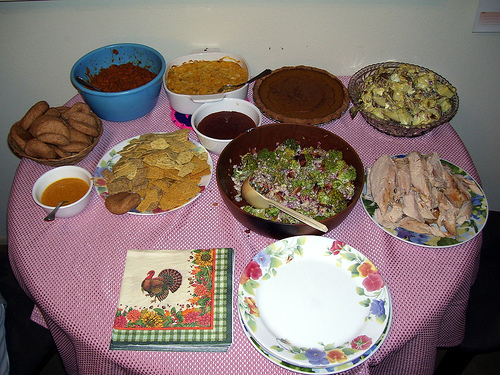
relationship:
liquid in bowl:
[199, 110, 253, 140] [24, 163, 96, 229]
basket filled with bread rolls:
[27, 115, 104, 165] [6, 100, 95, 160]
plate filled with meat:
[368, 152, 488, 246] [373, 153, 473, 237]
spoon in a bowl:
[240, 177, 329, 233] [212, 121, 369, 246]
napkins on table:
[73, 220, 258, 368] [25, 227, 110, 323]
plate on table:
[93, 131, 489, 374] [7, 75, 482, 373]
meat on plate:
[364, 143, 490, 244] [357, 140, 498, 273]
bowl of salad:
[215, 120, 364, 240] [229, 138, 356, 223]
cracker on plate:
[144, 133, 169, 153] [91, 131, 215, 216]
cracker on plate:
[102, 127, 206, 215] [91, 131, 215, 216]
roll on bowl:
[9, 101, 99, 159] [6, 114, 103, 166]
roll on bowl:
[20, 99, 47, 129] [6, 114, 103, 166]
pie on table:
[249, 61, 355, 127] [7, 75, 482, 373]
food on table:
[6, 42, 488, 249] [7, 75, 482, 373]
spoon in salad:
[224, 181, 338, 236] [232, 127, 352, 232]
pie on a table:
[251, 65, 353, 128] [70, 240, 107, 366]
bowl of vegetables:
[6, 43, 490, 375] [357, 59, 454, 139]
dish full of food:
[347, 57, 463, 139] [362, 69, 449, 121]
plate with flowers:
[93, 131, 489, 374] [234, 144, 345, 214]